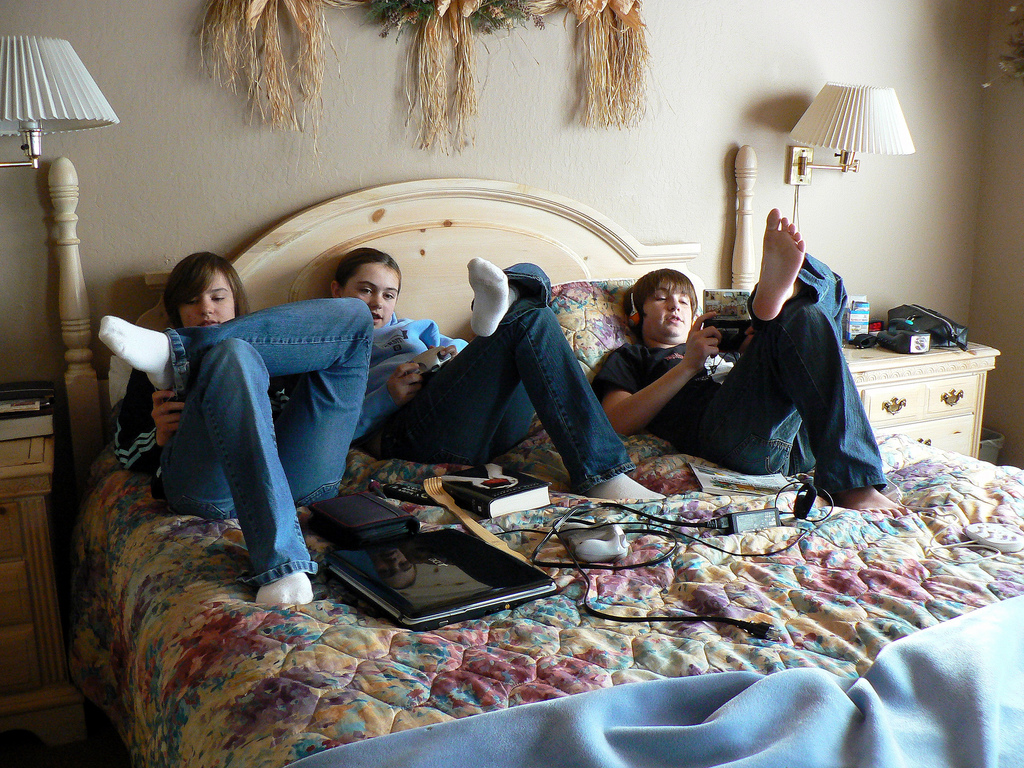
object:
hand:
[470, 478, 514, 490]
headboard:
[210, 176, 702, 359]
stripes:
[113, 414, 159, 471]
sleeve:
[109, 366, 160, 475]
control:
[381, 480, 446, 506]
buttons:
[409, 492, 413, 496]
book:
[432, 461, 553, 521]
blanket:
[288, 585, 1021, 765]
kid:
[91, 250, 371, 613]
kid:
[322, 246, 666, 503]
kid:
[586, 206, 911, 520]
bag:
[885, 299, 968, 355]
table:
[835, 340, 1002, 461]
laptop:
[317, 523, 560, 632]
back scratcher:
[421, 475, 550, 577]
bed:
[39, 144, 1022, 765]